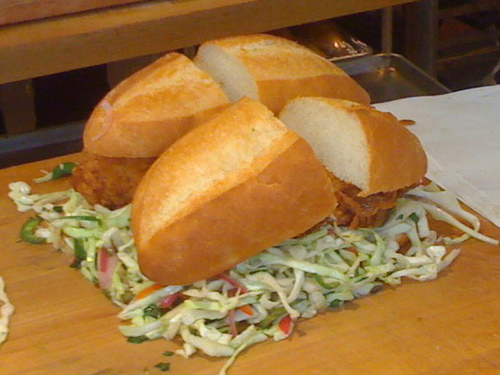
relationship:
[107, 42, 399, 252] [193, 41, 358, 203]
bread cut half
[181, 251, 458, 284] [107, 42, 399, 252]
vegetables under bread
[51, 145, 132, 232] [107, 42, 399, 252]
meat under bread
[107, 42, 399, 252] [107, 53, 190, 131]
bread has crust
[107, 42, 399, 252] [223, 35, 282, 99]
bread has indent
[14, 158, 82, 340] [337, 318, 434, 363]
board has lines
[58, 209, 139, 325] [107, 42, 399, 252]
lettuce under bread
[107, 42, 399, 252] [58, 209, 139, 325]
bread on lettuce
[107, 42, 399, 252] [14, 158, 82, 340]
bread on board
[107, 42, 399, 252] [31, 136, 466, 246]
bread on table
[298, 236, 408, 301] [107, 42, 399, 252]
cabbage under bread